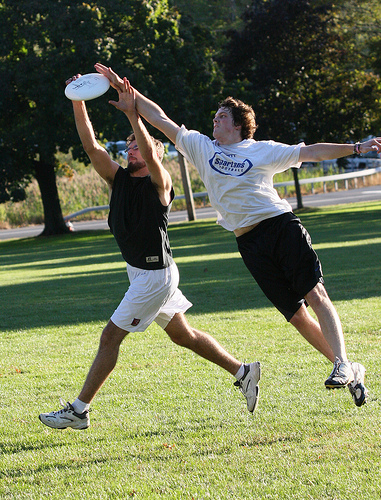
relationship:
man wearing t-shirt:
[40, 62, 263, 434] [106, 164, 173, 269]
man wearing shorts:
[40, 62, 263, 434] [108, 258, 194, 335]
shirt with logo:
[170, 128, 305, 233] [211, 148, 254, 180]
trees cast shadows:
[4, 0, 379, 249] [0, 197, 381, 333]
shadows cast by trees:
[0, 197, 381, 333] [4, 0, 379, 249]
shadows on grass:
[0, 197, 381, 333] [4, 197, 381, 491]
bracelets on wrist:
[354, 141, 363, 155] [351, 143, 365, 155]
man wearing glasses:
[40, 62, 263, 434] [124, 146, 138, 152]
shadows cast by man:
[0, 197, 381, 333] [40, 62, 263, 434]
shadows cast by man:
[0, 197, 381, 333] [91, 62, 381, 407]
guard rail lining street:
[64, 155, 380, 232] [2, 181, 379, 243]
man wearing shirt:
[91, 62, 381, 407] [170, 130, 304, 233]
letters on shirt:
[207, 150, 255, 175] [170, 130, 304, 233]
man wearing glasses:
[40, 62, 263, 434] [126, 143, 144, 157]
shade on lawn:
[6, 199, 379, 334] [4, 197, 381, 491]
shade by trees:
[6, 199, 379, 334] [4, 0, 379, 249]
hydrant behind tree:
[66, 223, 76, 234] [2, 0, 189, 242]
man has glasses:
[40, 62, 263, 434] [126, 143, 144, 157]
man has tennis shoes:
[40, 62, 263, 434] [37, 361, 261, 429]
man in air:
[40, 62, 263, 434] [4, 4, 379, 493]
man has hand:
[91, 62, 381, 407] [96, 58, 121, 88]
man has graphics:
[91, 62, 381, 407] [207, 152, 255, 176]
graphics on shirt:
[207, 152, 255, 176] [170, 130, 304, 233]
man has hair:
[91, 62, 381, 407] [220, 93, 256, 141]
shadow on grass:
[0, 197, 381, 333] [4, 197, 381, 491]